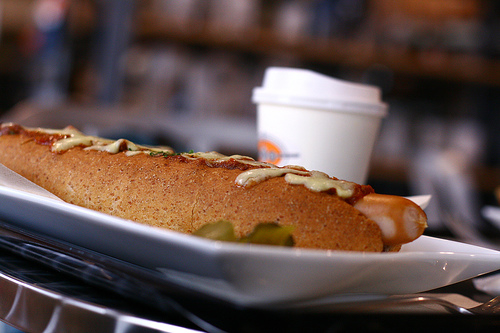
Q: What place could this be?
A: It is a restaurant.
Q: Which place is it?
A: It is a restaurant.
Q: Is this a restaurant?
A: Yes, it is a restaurant.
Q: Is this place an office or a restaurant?
A: It is a restaurant.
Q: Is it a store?
A: No, it is a restaurant.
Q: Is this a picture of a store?
A: No, the picture is showing a restaurant.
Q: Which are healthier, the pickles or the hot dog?
A: The pickles are healthier than the hot dog.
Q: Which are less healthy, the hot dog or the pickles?
A: The hot dog are less healthy than the pickles.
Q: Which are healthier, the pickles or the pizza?
A: The pickles are healthier than the pizza.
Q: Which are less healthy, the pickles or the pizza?
A: The pizza are less healthy than the pickles.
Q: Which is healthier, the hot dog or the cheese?
A: The cheese is healthier than the hot dog.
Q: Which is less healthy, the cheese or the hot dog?
A: The hot dog is less healthy than the cheese.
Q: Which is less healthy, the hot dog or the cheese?
A: The hot dog is less healthy than the cheese.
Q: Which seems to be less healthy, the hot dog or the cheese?
A: The hot dog is less healthy than the cheese.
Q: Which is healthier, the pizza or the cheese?
A: The cheese is healthier than the pizza.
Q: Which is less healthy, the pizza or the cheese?
A: The pizza is less healthy than the cheese.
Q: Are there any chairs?
A: No, there are no chairs.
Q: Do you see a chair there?
A: No, there are no chairs.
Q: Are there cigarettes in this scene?
A: No, there are no cigarettes.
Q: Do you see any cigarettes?
A: No, there are no cigarettes.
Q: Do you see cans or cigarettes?
A: No, there are no cigarettes or cans.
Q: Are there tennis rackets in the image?
A: No, there are no tennis rackets.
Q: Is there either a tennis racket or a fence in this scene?
A: No, there are no rackets or fences.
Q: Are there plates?
A: Yes, there is a plate.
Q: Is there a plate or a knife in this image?
A: Yes, there is a plate.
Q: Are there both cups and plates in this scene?
A: Yes, there are both a plate and a cup.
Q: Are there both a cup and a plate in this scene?
A: Yes, there are both a plate and a cup.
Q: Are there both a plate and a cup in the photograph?
A: Yes, there are both a plate and a cup.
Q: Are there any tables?
A: Yes, there is a table.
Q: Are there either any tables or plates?
A: Yes, there is a table.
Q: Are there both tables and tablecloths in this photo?
A: No, there is a table but no tablecloths.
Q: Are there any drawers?
A: No, there are no drawers.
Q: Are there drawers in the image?
A: No, there are no drawers.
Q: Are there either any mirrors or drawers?
A: No, there are no drawers or mirrors.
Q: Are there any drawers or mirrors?
A: No, there are no drawers or mirrors.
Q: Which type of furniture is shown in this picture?
A: The furniture is a table.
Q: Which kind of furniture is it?
A: The piece of furniture is a table.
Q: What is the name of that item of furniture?
A: This is a table.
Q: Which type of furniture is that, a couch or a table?
A: This is a table.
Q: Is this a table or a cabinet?
A: This is a table.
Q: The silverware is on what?
A: The silverware is on the plate.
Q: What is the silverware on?
A: The silverware is on the plate.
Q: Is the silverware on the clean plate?
A: Yes, the silverware is on the plate.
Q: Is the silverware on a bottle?
A: No, the silverware is on the plate.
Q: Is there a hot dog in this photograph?
A: Yes, there is a hot dog.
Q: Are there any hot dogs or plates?
A: Yes, there is a hot dog.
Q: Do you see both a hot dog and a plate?
A: Yes, there are both a hot dog and a plate.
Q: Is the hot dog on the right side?
A: Yes, the hot dog is on the right of the image.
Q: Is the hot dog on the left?
A: No, the hot dog is on the right of the image.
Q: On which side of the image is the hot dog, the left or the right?
A: The hot dog is on the right of the image.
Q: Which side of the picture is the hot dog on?
A: The hot dog is on the right of the image.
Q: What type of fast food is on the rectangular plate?
A: The food is a hot dog.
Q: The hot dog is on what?
A: The hot dog is on the plate.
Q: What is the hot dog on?
A: The hot dog is on the plate.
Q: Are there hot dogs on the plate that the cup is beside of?
A: Yes, there is a hot dog on the plate.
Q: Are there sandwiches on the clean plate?
A: No, there is a hot dog on the plate.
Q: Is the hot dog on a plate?
A: Yes, the hot dog is on a plate.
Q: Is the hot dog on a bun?
A: No, the hot dog is on a plate.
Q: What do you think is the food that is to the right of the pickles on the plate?
A: The food is a hot dog.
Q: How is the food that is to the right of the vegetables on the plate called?
A: The food is a hot dog.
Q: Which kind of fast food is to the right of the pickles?
A: The food is a hot dog.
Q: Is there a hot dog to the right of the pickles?
A: Yes, there is a hot dog to the right of the pickles.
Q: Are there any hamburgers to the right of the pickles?
A: No, there is a hot dog to the right of the pickles.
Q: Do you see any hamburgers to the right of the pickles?
A: No, there is a hot dog to the right of the pickles.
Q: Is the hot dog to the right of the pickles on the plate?
A: Yes, the hot dog is to the right of the pickles.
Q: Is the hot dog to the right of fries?
A: No, the hot dog is to the right of the pickles.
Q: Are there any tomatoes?
A: No, there are no tomatoes.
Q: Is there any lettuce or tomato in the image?
A: No, there are no tomatoes or lettuce.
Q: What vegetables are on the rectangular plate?
A: The vegetables are pickles.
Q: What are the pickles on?
A: The pickles are on the plate.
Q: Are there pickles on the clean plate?
A: Yes, there are pickles on the plate.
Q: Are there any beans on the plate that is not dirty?
A: No, there are pickles on the plate.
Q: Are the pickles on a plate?
A: Yes, the pickles are on a plate.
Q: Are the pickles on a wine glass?
A: No, the pickles are on a plate.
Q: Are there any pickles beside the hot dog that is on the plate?
A: Yes, there are pickles beside the hot dog.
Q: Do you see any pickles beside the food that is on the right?
A: Yes, there are pickles beside the hot dog.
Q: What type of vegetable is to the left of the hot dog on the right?
A: The vegetables are pickles.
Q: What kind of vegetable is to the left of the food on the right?
A: The vegetables are pickles.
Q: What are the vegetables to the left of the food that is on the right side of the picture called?
A: The vegetables are pickles.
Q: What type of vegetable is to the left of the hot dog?
A: The vegetables are pickles.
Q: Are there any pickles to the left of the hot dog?
A: Yes, there are pickles to the left of the hot dog.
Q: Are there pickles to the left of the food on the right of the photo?
A: Yes, there are pickles to the left of the hot dog.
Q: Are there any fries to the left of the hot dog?
A: No, there are pickles to the left of the hot dog.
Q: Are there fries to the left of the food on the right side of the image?
A: No, there are pickles to the left of the hot dog.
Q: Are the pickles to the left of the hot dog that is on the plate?
A: Yes, the pickles are to the left of the hot dog.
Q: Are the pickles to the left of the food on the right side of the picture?
A: Yes, the pickles are to the left of the hot dog.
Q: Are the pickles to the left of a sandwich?
A: No, the pickles are to the left of the hot dog.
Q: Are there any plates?
A: Yes, there is a plate.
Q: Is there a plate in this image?
A: Yes, there is a plate.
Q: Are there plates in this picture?
A: Yes, there is a plate.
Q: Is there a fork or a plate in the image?
A: Yes, there is a plate.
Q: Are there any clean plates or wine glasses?
A: Yes, there is a clean plate.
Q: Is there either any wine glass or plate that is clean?
A: Yes, the plate is clean.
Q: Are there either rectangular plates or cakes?
A: Yes, there is a rectangular plate.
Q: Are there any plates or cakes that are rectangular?
A: Yes, the plate is rectangular.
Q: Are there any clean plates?
A: Yes, there is a clean plate.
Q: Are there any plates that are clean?
A: Yes, there is a plate that is clean.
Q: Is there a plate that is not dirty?
A: Yes, there is a clean plate.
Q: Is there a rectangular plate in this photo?
A: Yes, there is a rectangular plate.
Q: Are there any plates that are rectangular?
A: Yes, there is a plate that is rectangular.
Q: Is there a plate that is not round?
A: Yes, there is a rectangular plate.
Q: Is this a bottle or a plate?
A: This is a plate.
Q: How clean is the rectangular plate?
A: The plate is clean.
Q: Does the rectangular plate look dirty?
A: No, the plate is clean.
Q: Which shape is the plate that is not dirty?
A: The plate is rectangular.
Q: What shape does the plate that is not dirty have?
A: The plate has rectangular shape.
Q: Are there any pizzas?
A: Yes, there is a pizza.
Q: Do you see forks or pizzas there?
A: Yes, there is a pizza.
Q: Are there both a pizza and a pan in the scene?
A: No, there is a pizza but no pans.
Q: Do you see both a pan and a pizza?
A: No, there is a pizza but no pans.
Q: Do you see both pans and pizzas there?
A: No, there is a pizza but no pans.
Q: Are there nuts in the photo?
A: No, there are no nuts.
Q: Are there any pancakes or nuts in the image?
A: No, there are no nuts or pancakes.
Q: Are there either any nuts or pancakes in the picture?
A: No, there are no nuts or pancakes.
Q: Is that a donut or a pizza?
A: That is a pizza.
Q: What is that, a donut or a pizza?
A: That is a pizza.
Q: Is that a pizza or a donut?
A: That is a pizza.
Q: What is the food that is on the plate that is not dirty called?
A: The food is a pizza.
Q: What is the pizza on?
A: The pizza is on the plate.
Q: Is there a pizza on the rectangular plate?
A: Yes, there is a pizza on the plate.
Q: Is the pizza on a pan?
A: No, the pizza is on the plate.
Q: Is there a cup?
A: Yes, there is a cup.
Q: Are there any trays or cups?
A: Yes, there is a cup.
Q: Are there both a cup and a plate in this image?
A: Yes, there are both a cup and a plate.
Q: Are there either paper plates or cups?
A: Yes, there is a paper cup.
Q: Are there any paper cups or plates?
A: Yes, there is a paper cup.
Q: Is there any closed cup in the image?
A: Yes, there is a closed cup.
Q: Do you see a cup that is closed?
A: Yes, there is a cup that is closed.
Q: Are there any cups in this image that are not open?
A: Yes, there is an closed cup.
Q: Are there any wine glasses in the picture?
A: No, there are no wine glasses.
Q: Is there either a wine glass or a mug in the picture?
A: No, there are no wine glasses or mugs.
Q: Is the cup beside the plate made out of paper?
A: Yes, the cup is made of paper.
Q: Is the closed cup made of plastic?
A: No, the cup is made of paper.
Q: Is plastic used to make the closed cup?
A: No, the cup is made of paper.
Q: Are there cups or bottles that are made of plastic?
A: No, there is a cup but it is made of paper.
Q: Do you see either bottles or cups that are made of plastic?
A: No, there is a cup but it is made of paper.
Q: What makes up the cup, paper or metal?
A: The cup is made of paper.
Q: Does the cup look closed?
A: Yes, the cup is closed.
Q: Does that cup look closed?
A: Yes, the cup is closed.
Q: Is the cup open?
A: No, the cup is closed.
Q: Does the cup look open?
A: No, the cup is closed.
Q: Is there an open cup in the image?
A: No, there is a cup but it is closed.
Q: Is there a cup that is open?
A: No, there is a cup but it is closed.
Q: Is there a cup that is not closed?
A: No, there is a cup but it is closed.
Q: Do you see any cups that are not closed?
A: No, there is a cup but it is closed.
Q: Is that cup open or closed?
A: The cup is closed.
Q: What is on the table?
A: The cup is on the table.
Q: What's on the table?
A: The cup is on the table.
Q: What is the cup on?
A: The cup is on the table.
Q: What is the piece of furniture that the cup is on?
A: The piece of furniture is a table.